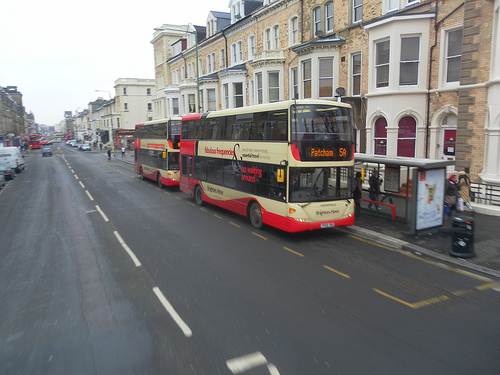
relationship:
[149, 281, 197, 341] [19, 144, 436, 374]
line in street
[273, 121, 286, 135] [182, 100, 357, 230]
windows on bus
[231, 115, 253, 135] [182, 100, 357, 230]
windows on bus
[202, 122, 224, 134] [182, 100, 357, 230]
windows on bus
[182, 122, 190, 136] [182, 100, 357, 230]
windows on bus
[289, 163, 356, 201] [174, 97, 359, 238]
windshield on bus